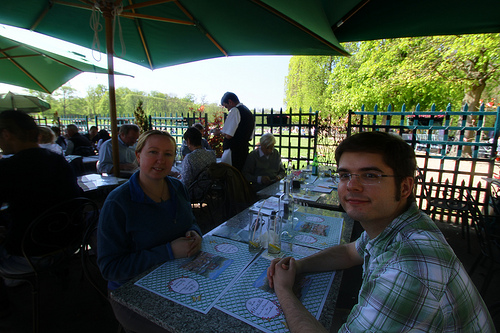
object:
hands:
[170, 225, 202, 264]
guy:
[267, 132, 496, 332]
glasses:
[332, 167, 405, 182]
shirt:
[331, 199, 495, 331]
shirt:
[97, 136, 138, 173]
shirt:
[3, 148, 75, 253]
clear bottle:
[278, 177, 294, 240]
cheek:
[392, 184, 406, 202]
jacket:
[94, 167, 204, 292]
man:
[262, 131, 495, 331]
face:
[331, 153, 395, 222]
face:
[139, 132, 176, 178]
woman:
[93, 126, 208, 333]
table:
[100, 199, 362, 333]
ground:
[0, 0, 500, 333]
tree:
[276, 31, 500, 159]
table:
[249, 155, 350, 212]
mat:
[119, 232, 265, 317]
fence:
[37, 105, 487, 220]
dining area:
[1, 155, 371, 333]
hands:
[266, 252, 298, 294]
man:
[0, 108, 82, 261]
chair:
[18, 192, 106, 327]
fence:
[0, 103, 498, 236]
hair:
[126, 126, 183, 154]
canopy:
[0, 0, 357, 74]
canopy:
[0, 33, 137, 95]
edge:
[103, 287, 264, 333]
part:
[436, 116, 485, 181]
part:
[389, 257, 445, 305]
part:
[107, 215, 133, 253]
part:
[77, 252, 102, 287]